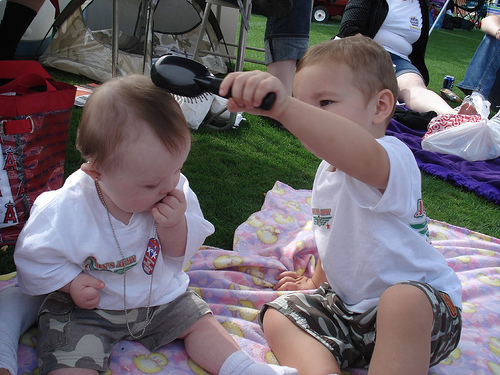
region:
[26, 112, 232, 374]
The baby has a necklace on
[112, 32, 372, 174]
The boy has a hair brush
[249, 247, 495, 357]
The boy has shorts on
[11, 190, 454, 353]
The children are sitting on a blanket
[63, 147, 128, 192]
The baby has her ears peirced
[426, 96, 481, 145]
A Target bag is in the back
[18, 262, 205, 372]
The baby has camo shorts on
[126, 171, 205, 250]
The baby has her hand to her face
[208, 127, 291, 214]
The grass is green and mowed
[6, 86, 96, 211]
A red bag is in the back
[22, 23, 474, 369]
two young children sitting on a blanket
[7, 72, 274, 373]
baby wearing white T-shirt and camouflage pants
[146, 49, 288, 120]
black hairbrush in a child's left hand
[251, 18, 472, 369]
toddler wearing white T-shirt and camouflage shorts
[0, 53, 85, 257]
red tote bag with LA Angels logos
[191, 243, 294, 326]
blanket with pink, purple and yellow duckling pattern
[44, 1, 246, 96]
small dome tent with mesh sides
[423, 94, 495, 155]
plastic Target shopping bag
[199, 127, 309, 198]
green lawn with shadow and sunlight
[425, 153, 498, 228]
blue blanket on a lawn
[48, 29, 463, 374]
two children on blanket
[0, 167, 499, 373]
the blanket on the grass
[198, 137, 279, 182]
the grass is green and cut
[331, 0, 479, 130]
the woman sitting on the blanket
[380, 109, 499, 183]
the blanket is purple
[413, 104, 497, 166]
the target bag on the blanket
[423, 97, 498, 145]
the target bag is plastic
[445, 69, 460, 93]
the soda can on the grass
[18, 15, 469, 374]
the child brushing the hair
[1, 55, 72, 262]
the red bag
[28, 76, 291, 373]
a baby sitting on blanket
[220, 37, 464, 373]
a baby sitting on blanket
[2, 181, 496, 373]
a yellow duck blanket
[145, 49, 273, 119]
a black hair brush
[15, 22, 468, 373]
a baby combing another baby's hair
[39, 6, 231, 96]
a pop up tent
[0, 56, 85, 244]
a bright red bag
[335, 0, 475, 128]
a woman sitting on a blanket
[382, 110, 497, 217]
a purple blanket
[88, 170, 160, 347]
a silver necklace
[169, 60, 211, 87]
brush in child's hand.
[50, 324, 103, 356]
shorts on young child.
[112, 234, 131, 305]
necklace on the child.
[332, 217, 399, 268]
white shirt on child.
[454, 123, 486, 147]
white plastic bag on towel.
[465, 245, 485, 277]
blanket on the ground.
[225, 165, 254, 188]
grass on the ground.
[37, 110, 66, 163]
red bag on the ground.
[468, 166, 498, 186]
purple blanket on the grass.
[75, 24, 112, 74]
tent on the grass.